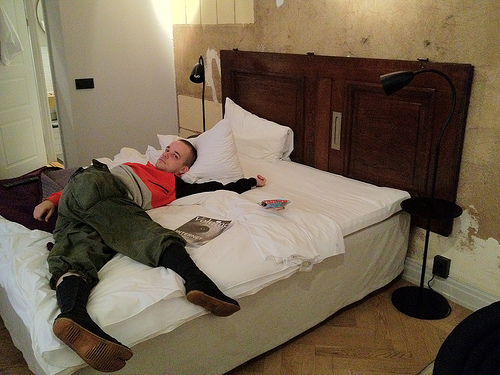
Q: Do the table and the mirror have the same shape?
A: Yes, both the table and the mirror are round.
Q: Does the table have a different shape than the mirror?
A: No, both the table and the mirror are round.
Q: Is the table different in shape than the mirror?
A: No, both the table and the mirror are round.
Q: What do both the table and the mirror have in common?
A: The shape, both the table and the mirror are round.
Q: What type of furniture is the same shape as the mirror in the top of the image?
A: The table is the same shape as the mirror.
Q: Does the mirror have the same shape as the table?
A: Yes, both the mirror and the table are round.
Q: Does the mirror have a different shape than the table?
A: No, both the mirror and the table are round.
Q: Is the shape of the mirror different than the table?
A: No, both the mirror and the table are round.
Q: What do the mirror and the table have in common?
A: The shape, both the mirror and the table are round.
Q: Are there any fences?
A: No, there are no fences.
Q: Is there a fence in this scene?
A: No, there are no fences.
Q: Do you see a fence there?
A: No, there are no fences.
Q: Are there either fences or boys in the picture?
A: No, there are no fences or boys.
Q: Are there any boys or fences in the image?
A: No, there are no fences or boys.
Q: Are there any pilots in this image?
A: No, there are no pilots.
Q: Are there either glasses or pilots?
A: No, there are no pilots or glasses.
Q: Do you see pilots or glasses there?
A: No, there are no pilots or glasses.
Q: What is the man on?
A: The man is on the bed.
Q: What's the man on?
A: The man is on the bed.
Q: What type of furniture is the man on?
A: The man is on the bed.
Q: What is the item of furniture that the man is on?
A: The piece of furniture is a bed.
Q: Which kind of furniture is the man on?
A: The man is on the bed.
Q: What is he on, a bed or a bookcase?
A: The man is on a bed.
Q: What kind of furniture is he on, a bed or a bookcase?
A: The man is on a bed.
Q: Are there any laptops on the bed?
A: No, there is a man on the bed.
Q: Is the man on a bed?
A: Yes, the man is on a bed.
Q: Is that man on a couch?
A: No, the man is on a bed.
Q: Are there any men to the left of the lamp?
A: Yes, there is a man to the left of the lamp.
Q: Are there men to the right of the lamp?
A: No, the man is to the left of the lamp.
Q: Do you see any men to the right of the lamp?
A: No, the man is to the left of the lamp.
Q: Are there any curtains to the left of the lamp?
A: No, there is a man to the left of the lamp.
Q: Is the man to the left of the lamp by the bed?
A: Yes, the man is to the left of the lamp.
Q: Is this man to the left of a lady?
A: No, the man is to the left of the lamp.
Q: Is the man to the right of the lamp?
A: No, the man is to the left of the lamp.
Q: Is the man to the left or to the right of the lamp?
A: The man is to the left of the lamp.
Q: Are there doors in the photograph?
A: Yes, there is a door.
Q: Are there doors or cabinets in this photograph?
A: Yes, there is a door.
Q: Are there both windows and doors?
A: No, there is a door but no windows.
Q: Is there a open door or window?
A: Yes, there is an open door.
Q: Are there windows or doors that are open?
A: Yes, the door is open.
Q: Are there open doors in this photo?
A: Yes, there is an open door.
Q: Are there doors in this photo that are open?
A: Yes, there is a door that is open.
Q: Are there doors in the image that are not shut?
A: Yes, there is a open door.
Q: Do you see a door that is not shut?
A: Yes, there is a open door.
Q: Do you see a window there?
A: No, there are no windows.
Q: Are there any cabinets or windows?
A: No, there are no windows or cabinets.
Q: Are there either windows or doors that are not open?
A: No, there is a door but it is open.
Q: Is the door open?
A: Yes, the door is open.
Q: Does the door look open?
A: Yes, the door is open.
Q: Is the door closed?
A: No, the door is open.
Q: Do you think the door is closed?
A: No, the door is open.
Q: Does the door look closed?
A: No, the door is open.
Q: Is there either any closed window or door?
A: No, there is a door but it is open.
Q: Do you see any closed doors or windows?
A: No, there is a door but it is open.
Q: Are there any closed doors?
A: No, there is a door but it is open.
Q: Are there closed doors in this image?
A: No, there is a door but it is open.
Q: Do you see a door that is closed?
A: No, there is a door but it is open.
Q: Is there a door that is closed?
A: No, there is a door but it is open.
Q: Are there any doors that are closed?
A: No, there is a door but it is open.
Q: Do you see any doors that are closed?
A: No, there is a door but it is open.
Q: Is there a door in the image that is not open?
A: No, there is a door but it is open.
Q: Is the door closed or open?
A: The door is open.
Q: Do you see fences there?
A: No, there are no fences.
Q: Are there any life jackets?
A: No, there are no life jackets.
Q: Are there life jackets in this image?
A: No, there are no life jackets.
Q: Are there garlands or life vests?
A: No, there are no life vests or garlands.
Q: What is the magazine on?
A: The magazine is on the bed.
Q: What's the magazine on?
A: The magazine is on the bed.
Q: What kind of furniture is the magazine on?
A: The magazine is on the bed.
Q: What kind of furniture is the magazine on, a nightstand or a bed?
A: The magazine is on a bed.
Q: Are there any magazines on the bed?
A: Yes, there is a magazine on the bed.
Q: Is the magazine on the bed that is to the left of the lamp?
A: Yes, the magazine is on the bed.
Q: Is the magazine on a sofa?
A: No, the magazine is on the bed.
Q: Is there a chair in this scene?
A: No, there are no chairs.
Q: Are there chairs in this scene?
A: No, there are no chairs.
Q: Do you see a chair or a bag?
A: No, there are no chairs or bags.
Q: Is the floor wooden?
A: Yes, the floor is wooden.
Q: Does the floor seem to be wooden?
A: Yes, the floor is wooden.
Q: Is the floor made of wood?
A: Yes, the floor is made of wood.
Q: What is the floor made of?
A: The floor is made of wood.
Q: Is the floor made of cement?
A: No, the floor is made of wood.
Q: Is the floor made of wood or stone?
A: The floor is made of wood.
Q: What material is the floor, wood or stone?
A: The floor is made of wood.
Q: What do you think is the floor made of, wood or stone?
A: The floor is made of wood.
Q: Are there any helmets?
A: No, there are no helmets.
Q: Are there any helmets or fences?
A: No, there are no helmets or fences.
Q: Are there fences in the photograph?
A: No, there are no fences.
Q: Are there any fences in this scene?
A: No, there are no fences.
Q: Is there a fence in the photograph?
A: No, there are no fences.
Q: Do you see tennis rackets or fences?
A: No, there are no fences or tennis rackets.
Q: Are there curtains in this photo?
A: No, there are no curtains.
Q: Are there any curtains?
A: No, there are no curtains.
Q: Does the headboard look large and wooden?
A: Yes, the headboard is large and wooden.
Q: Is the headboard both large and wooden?
A: Yes, the headboard is large and wooden.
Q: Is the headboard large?
A: Yes, the headboard is large.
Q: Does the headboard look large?
A: Yes, the headboard is large.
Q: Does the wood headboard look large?
A: Yes, the headboard is large.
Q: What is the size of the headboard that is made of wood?
A: The headboard is large.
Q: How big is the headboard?
A: The headboard is large.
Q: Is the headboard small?
A: No, the headboard is large.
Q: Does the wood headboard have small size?
A: No, the headboard is large.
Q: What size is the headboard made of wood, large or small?
A: The head board is large.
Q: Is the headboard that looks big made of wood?
A: Yes, the headboard is made of wood.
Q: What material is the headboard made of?
A: The headboard is made of wood.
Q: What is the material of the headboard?
A: The headboard is made of wood.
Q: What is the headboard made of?
A: The headboard is made of wood.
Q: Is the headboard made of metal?
A: No, the headboard is made of wood.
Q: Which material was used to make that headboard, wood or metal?
A: The headboard is made of wood.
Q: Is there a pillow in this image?
A: Yes, there is a pillow.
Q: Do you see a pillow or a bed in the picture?
A: Yes, there is a pillow.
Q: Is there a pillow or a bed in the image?
A: Yes, there is a pillow.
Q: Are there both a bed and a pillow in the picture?
A: Yes, there are both a pillow and a bed.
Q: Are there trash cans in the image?
A: No, there are no trash cans.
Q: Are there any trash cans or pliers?
A: No, there are no trash cans or pliers.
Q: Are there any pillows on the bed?
A: Yes, there is a pillow on the bed.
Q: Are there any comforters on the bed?
A: No, there is a pillow on the bed.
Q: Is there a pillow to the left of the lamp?
A: Yes, there is a pillow to the left of the lamp.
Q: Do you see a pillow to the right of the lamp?
A: No, the pillow is to the left of the lamp.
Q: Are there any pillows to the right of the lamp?
A: No, the pillow is to the left of the lamp.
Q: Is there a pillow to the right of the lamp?
A: No, the pillow is to the left of the lamp.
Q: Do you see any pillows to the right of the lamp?
A: No, the pillow is to the left of the lamp.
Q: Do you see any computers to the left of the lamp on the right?
A: No, there is a pillow to the left of the lamp.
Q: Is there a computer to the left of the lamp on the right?
A: No, there is a pillow to the left of the lamp.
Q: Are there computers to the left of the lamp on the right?
A: No, there is a pillow to the left of the lamp.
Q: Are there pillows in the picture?
A: Yes, there is a pillow.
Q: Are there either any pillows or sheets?
A: Yes, there is a pillow.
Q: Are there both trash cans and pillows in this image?
A: No, there is a pillow but no trash cans.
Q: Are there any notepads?
A: No, there are no notepads.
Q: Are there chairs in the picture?
A: No, there are no chairs.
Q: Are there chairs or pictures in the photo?
A: No, there are no chairs or pictures.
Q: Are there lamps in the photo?
A: Yes, there is a lamp.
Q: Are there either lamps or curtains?
A: Yes, there is a lamp.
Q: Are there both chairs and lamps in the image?
A: No, there is a lamp but no chairs.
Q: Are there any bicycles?
A: No, there are no bicycles.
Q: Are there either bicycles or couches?
A: No, there are no bicycles or couches.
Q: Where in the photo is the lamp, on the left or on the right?
A: The lamp is on the right of the image.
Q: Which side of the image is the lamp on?
A: The lamp is on the right of the image.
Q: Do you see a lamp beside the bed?
A: Yes, there is a lamp beside the bed.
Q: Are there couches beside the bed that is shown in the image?
A: No, there is a lamp beside the bed.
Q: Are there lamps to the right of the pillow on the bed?
A: Yes, there is a lamp to the right of the pillow.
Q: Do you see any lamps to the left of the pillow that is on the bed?
A: No, the lamp is to the right of the pillow.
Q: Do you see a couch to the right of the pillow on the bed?
A: No, there is a lamp to the right of the pillow.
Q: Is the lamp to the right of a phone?
A: No, the lamp is to the right of the pillow.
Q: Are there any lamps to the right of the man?
A: Yes, there is a lamp to the right of the man.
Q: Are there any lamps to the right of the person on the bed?
A: Yes, there is a lamp to the right of the man.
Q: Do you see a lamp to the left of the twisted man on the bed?
A: No, the lamp is to the right of the man.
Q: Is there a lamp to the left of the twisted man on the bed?
A: No, the lamp is to the right of the man.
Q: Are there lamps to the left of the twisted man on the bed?
A: No, the lamp is to the right of the man.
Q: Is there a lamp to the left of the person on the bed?
A: No, the lamp is to the right of the man.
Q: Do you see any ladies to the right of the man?
A: No, there is a lamp to the right of the man.